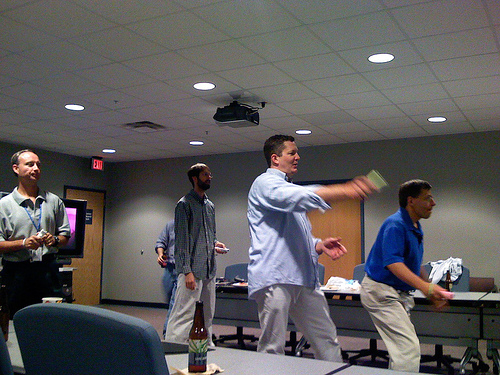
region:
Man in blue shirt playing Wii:
[244, 133, 388, 364]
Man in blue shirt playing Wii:
[358, 178, 454, 373]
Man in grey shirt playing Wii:
[162, 162, 230, 352]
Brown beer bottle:
[189, 298, 209, 373]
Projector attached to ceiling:
[211, 100, 261, 129]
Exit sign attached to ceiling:
[89, 155, 106, 172]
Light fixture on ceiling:
[192, 79, 217, 93]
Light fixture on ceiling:
[366, 52, 395, 64]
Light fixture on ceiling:
[427, 114, 447, 127]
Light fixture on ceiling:
[64, 102, 85, 113]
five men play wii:
[0, 147, 461, 362]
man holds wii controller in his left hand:
[210, 232, 230, 253]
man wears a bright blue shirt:
[362, 176, 427, 281]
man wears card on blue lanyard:
[0, 145, 70, 270]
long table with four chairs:
[215, 272, 475, 344]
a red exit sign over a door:
[91, 155, 101, 170]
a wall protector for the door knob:
[135, 246, 145, 256]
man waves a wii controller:
[245, 135, 385, 280]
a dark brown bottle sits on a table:
[185, 300, 205, 370]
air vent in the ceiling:
[118, 121, 168, 138]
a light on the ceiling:
[65, 99, 81, 113]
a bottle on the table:
[190, 301, 211, 370]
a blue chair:
[19, 300, 151, 367]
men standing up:
[12, 121, 470, 373]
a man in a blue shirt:
[351, 179, 437, 371]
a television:
[59, 196, 95, 261]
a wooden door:
[66, 184, 103, 301]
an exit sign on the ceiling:
[90, 155, 104, 167]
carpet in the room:
[93, 295, 171, 330]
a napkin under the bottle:
[180, 356, 219, 373]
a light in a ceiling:
[368, 49, 396, 67]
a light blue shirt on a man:
[239, 166, 325, 293]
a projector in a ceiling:
[210, 95, 275, 133]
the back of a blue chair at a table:
[12, 301, 169, 374]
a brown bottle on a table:
[185, 297, 210, 373]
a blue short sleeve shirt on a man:
[361, 207, 429, 290]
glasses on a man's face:
[201, 169, 215, 181]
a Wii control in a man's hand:
[213, 244, 233, 255]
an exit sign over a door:
[87, 153, 108, 173]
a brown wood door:
[60, 185, 110, 303]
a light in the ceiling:
[360, 50, 399, 67]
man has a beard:
[195, 177, 209, 189]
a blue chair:
[27, 309, 122, 338]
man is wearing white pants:
[179, 295, 189, 326]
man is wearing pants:
[255, 301, 286, 349]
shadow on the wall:
[117, 174, 151, 202]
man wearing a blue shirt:
[382, 217, 404, 253]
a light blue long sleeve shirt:
[266, 225, 304, 268]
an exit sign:
[91, 153, 108, 173]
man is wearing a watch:
[49, 234, 64, 245]